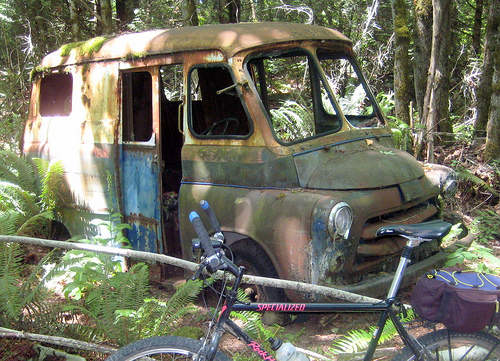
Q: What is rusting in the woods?
A: Car.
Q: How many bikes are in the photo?
A: One.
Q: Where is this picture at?
A: Forest.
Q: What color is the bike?
A: Black.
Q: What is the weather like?
A: Sunny.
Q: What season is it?
A: Summer.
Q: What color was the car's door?
A: Blue.